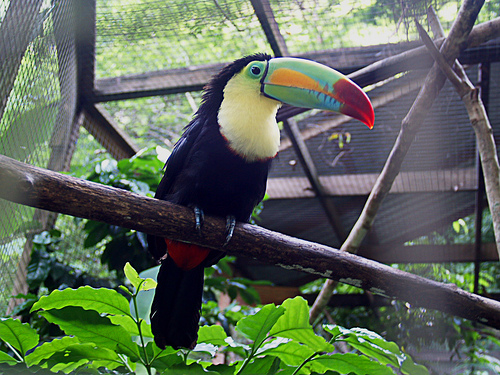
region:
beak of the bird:
[257, 48, 389, 152]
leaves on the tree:
[26, 284, 328, 369]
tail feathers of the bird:
[125, 247, 228, 363]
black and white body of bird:
[128, 50, 285, 228]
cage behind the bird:
[3, 40, 106, 133]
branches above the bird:
[379, 19, 486, 144]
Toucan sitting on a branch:
[149, 53, 378, 348]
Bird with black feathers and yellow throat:
[157, 50, 375, 347]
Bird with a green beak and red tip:
[208, 53, 381, 130]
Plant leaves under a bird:
[0, 258, 432, 373]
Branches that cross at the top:
[304, 0, 497, 336]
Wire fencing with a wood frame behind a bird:
[1, 0, 499, 307]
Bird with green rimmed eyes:
[151, 50, 375, 348]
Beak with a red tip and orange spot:
[260, 54, 376, 129]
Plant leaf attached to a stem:
[30, 285, 133, 325]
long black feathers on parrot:
[153, 46, 275, 340]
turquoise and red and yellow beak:
[262, 55, 390, 126]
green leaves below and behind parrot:
[1, 141, 498, 371]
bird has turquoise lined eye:
[251, 63, 264, 81]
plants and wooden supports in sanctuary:
[13, 13, 498, 356]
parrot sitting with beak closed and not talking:
[140, 43, 385, 353]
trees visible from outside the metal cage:
[1, 0, 498, 311]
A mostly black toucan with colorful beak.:
[145, 53, 375, 352]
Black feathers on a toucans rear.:
[148, 254, 204, 354]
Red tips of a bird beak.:
[335, 77, 375, 128]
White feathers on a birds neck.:
[217, 59, 281, 159]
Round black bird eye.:
[249, 65, 259, 75]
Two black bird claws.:
[186, 203, 236, 246]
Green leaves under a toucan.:
[1, 262, 430, 374]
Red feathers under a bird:
[166, 236, 209, 272]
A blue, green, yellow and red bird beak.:
[261, 54, 373, 129]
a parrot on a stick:
[167, 69, 292, 227]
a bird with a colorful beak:
[184, 30, 486, 224]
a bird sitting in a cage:
[166, 50, 333, 272]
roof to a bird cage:
[302, 77, 435, 254]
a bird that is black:
[162, 19, 372, 357]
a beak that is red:
[226, 28, 361, 173]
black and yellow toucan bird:
[140, 46, 380, 362]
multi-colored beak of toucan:
[259, 55, 379, 140]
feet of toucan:
[164, 201, 243, 259]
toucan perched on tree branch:
[4, 3, 496, 361]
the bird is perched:
[131, 50, 374, 350]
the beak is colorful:
[261, 55, 374, 127]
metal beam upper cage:
[73, 5, 100, 114]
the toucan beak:
[265, 59, 367, 131]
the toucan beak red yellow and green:
[273, 55, 378, 128]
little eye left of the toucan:
[249, 59, 266, 79]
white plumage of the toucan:
[228, 80, 274, 155]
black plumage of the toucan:
[187, 151, 264, 201]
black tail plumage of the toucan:
[165, 263, 201, 349]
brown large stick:
[409, 14, 499, 214]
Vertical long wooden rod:
[13, 188, 459, 295]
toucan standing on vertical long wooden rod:
[133, 33, 296, 331]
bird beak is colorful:
[262, 55, 374, 129]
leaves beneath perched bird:
[0, 259, 429, 373]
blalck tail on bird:
[147, 253, 203, 351]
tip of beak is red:
[332, 75, 375, 128]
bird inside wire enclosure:
[2, 0, 498, 372]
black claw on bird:
[190, 204, 204, 233]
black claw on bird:
[223, 213, 236, 246]